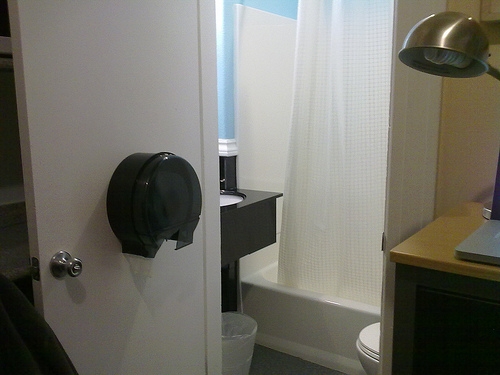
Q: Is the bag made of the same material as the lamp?
A: No, the bag is made of plastic and the lamp is made of metal.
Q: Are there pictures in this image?
A: No, there are no pictures.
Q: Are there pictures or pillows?
A: No, there are no pictures or pillows.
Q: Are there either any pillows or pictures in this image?
A: No, there are no pictures or pillows.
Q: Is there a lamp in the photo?
A: Yes, there is a lamp.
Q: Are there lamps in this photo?
A: Yes, there is a lamp.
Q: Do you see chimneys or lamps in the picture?
A: Yes, there is a lamp.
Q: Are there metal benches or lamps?
A: Yes, there is a metal lamp.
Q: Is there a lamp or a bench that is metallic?
A: Yes, the lamp is metallic.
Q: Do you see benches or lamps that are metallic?
A: Yes, the lamp is metallic.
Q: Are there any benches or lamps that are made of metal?
A: Yes, the lamp is made of metal.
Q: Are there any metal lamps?
A: Yes, there is a metal lamp.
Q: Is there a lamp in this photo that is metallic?
A: Yes, there is a lamp that is metallic.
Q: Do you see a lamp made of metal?
A: Yes, there is a lamp that is made of metal.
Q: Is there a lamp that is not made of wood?
A: Yes, there is a lamp that is made of metal.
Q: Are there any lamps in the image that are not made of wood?
A: Yes, there is a lamp that is made of metal.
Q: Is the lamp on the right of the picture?
A: Yes, the lamp is on the right of the image.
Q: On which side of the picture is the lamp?
A: The lamp is on the right of the image.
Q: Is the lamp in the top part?
A: Yes, the lamp is in the top of the image.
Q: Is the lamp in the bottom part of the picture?
A: No, the lamp is in the top of the image.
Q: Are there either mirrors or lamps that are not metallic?
A: No, there is a lamp but it is metallic.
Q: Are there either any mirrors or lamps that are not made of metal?
A: No, there is a lamp but it is made of metal.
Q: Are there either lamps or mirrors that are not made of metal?
A: No, there is a lamp but it is made of metal.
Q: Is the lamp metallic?
A: Yes, the lamp is metallic.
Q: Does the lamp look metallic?
A: Yes, the lamp is metallic.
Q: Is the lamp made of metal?
A: Yes, the lamp is made of metal.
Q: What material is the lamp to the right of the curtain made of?
A: The lamp is made of metal.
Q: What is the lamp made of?
A: The lamp is made of metal.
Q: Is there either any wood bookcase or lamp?
A: No, there is a lamp but it is metallic.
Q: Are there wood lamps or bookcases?
A: No, there is a lamp but it is metallic.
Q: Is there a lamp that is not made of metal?
A: No, there is a lamp but it is made of metal.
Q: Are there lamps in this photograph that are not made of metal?
A: No, there is a lamp but it is made of metal.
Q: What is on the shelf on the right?
A: The lamp is on the shelf.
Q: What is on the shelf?
A: The lamp is on the shelf.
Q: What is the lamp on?
A: The lamp is on the shelf.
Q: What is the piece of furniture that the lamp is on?
A: The piece of furniture is a shelf.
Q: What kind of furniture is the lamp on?
A: The lamp is on the shelf.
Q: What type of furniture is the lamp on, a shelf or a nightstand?
A: The lamp is on a shelf.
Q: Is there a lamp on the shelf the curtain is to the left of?
A: Yes, there is a lamp on the shelf.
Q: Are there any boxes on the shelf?
A: No, there is a lamp on the shelf.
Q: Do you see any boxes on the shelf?
A: No, there is a lamp on the shelf.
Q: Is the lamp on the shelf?
A: Yes, the lamp is on the shelf.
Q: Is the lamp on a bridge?
A: No, the lamp is on the shelf.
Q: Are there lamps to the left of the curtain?
A: No, the lamp is to the right of the curtain.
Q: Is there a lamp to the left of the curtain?
A: No, the lamp is to the right of the curtain.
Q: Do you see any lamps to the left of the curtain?
A: No, the lamp is to the right of the curtain.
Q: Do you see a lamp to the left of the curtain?
A: No, the lamp is to the right of the curtain.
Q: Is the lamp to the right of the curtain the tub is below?
A: Yes, the lamp is to the right of the curtain.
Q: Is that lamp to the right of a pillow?
A: No, the lamp is to the right of the curtain.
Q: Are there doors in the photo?
A: Yes, there is a door.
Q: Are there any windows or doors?
A: Yes, there is a door.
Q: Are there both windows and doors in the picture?
A: No, there is a door but no windows.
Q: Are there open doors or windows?
A: Yes, there is an open door.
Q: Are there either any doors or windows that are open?
A: Yes, the door is open.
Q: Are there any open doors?
A: Yes, there is an open door.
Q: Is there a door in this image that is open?
A: Yes, there is a door that is open.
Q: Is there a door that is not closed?
A: Yes, there is a open door.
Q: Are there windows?
A: No, there are no windows.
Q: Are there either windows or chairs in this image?
A: No, there are no windows or chairs.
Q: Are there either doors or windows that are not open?
A: No, there is a door but it is open.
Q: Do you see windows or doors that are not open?
A: No, there is a door but it is open.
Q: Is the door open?
A: Yes, the door is open.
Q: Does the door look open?
A: Yes, the door is open.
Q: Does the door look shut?
A: No, the door is open.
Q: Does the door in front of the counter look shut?
A: No, the door is open.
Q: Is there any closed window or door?
A: No, there is a door but it is open.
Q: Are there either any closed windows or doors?
A: No, there is a door but it is open.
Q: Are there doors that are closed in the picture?
A: No, there is a door but it is open.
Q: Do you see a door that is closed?
A: No, there is a door but it is open.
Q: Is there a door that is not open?
A: No, there is a door but it is open.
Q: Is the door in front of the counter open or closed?
A: The door is open.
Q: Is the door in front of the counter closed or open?
A: The door is open.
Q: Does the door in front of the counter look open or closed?
A: The door is open.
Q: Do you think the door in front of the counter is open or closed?
A: The door is open.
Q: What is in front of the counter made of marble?
A: The door is in front of the counter.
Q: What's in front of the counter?
A: The door is in front of the counter.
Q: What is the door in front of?
A: The door is in front of the counter.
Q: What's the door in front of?
A: The door is in front of the counter.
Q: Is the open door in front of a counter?
A: Yes, the door is in front of a counter.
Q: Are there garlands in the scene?
A: No, there are no garlands.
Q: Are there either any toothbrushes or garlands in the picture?
A: No, there are no garlands or toothbrushes.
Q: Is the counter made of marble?
A: Yes, the counter is made of marble.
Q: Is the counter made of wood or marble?
A: The counter is made of marble.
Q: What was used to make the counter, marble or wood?
A: The counter is made of marble.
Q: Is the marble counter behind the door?
A: Yes, the counter is behind the door.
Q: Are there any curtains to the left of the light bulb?
A: Yes, there is a curtain to the left of the light bulb.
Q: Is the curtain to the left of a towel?
A: No, the curtain is to the left of the light bulb.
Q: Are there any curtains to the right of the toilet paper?
A: Yes, there is a curtain to the right of the toilet paper.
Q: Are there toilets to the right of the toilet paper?
A: No, there is a curtain to the right of the toilet paper.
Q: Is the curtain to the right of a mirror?
A: No, the curtain is to the right of the toilet paper.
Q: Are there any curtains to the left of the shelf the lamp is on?
A: Yes, there is a curtain to the left of the shelf.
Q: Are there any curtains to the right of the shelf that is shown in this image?
A: No, the curtain is to the left of the shelf.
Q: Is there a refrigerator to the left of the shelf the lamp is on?
A: No, there is a curtain to the left of the shelf.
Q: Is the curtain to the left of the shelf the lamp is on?
A: Yes, the curtain is to the left of the shelf.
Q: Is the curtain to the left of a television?
A: No, the curtain is to the left of the shelf.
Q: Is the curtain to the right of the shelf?
A: No, the curtain is to the left of the shelf.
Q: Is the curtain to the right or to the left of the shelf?
A: The curtain is to the left of the shelf.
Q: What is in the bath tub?
A: The curtain is in the bath tub.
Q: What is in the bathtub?
A: The curtain is in the bath tub.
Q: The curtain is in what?
A: The curtain is in the bathtub.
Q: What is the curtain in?
A: The curtain is in the bathtub.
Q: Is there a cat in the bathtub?
A: No, there is a curtain in the bathtub.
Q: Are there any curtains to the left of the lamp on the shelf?
A: Yes, there is a curtain to the left of the lamp.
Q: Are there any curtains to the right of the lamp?
A: No, the curtain is to the left of the lamp.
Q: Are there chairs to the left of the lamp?
A: No, there is a curtain to the left of the lamp.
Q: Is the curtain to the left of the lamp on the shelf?
A: Yes, the curtain is to the left of the lamp.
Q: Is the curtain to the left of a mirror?
A: No, the curtain is to the left of the lamp.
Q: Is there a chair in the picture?
A: No, there are no chairs.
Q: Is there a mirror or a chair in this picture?
A: No, there are no chairs or mirrors.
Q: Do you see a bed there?
A: No, there are no beds.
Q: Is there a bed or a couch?
A: No, there are no beds or couches.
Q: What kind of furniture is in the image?
A: The furniture is a shelf.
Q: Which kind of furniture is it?
A: The piece of furniture is a shelf.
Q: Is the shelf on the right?
A: Yes, the shelf is on the right of the image.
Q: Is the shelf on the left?
A: No, the shelf is on the right of the image.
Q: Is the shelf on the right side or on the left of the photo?
A: The shelf is on the right of the image.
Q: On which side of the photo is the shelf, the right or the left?
A: The shelf is on the right of the image.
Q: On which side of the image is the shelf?
A: The shelf is on the right of the image.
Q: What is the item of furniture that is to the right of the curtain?
A: The piece of furniture is a shelf.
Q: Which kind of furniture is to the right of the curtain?
A: The piece of furniture is a shelf.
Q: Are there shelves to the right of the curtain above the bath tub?
A: Yes, there is a shelf to the right of the curtain.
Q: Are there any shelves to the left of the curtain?
A: No, the shelf is to the right of the curtain.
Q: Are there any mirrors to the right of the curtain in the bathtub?
A: No, there is a shelf to the right of the curtain.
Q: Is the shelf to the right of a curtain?
A: Yes, the shelf is to the right of a curtain.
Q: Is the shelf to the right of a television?
A: No, the shelf is to the right of a curtain.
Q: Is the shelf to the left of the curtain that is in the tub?
A: No, the shelf is to the right of the curtain.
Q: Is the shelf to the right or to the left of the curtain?
A: The shelf is to the right of the curtain.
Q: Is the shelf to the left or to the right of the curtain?
A: The shelf is to the right of the curtain.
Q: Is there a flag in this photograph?
A: No, there are no flags.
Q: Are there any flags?
A: No, there are no flags.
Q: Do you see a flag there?
A: No, there are no flags.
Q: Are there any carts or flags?
A: No, there are no flags or carts.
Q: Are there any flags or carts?
A: No, there are no flags or carts.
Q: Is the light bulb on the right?
A: Yes, the light bulb is on the right of the image.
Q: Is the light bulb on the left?
A: No, the light bulb is on the right of the image.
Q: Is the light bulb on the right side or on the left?
A: The light bulb is on the right of the image.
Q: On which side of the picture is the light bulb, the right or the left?
A: The light bulb is on the right of the image.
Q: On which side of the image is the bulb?
A: The bulb is on the right of the image.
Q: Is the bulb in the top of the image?
A: Yes, the bulb is in the top of the image.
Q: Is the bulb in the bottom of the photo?
A: No, the bulb is in the top of the image.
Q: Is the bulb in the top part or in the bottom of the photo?
A: The bulb is in the top of the image.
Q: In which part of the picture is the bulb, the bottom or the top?
A: The bulb is in the top of the image.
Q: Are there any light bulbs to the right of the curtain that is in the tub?
A: Yes, there is a light bulb to the right of the curtain.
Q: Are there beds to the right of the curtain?
A: No, there is a light bulb to the right of the curtain.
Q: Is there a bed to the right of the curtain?
A: No, there is a light bulb to the right of the curtain.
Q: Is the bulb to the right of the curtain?
A: Yes, the bulb is to the right of the curtain.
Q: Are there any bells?
A: No, there are no bells.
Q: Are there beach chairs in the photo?
A: No, there are no beach chairs.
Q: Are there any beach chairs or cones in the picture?
A: No, there are no beach chairs or cones.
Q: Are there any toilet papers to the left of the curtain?
A: Yes, there is a toilet paper to the left of the curtain.